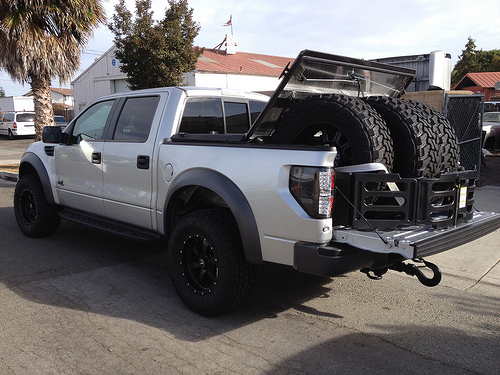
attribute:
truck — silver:
[9, 51, 496, 320]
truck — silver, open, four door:
[19, 35, 399, 285]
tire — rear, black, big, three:
[286, 99, 441, 225]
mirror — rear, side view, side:
[43, 121, 84, 142]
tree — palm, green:
[5, 13, 93, 149]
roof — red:
[172, 37, 298, 87]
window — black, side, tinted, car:
[190, 95, 255, 131]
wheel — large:
[316, 110, 438, 193]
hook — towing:
[381, 224, 451, 300]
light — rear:
[299, 174, 322, 192]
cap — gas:
[151, 150, 190, 186]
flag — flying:
[215, 9, 245, 45]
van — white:
[7, 87, 58, 125]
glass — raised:
[169, 76, 267, 157]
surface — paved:
[52, 264, 135, 325]